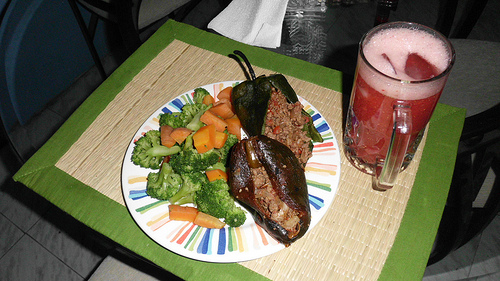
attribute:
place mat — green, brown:
[9, 15, 470, 279]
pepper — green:
[230, 48, 322, 165]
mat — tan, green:
[92, 43, 480, 280]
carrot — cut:
[173, 127, 187, 142]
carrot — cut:
[160, 125, 173, 142]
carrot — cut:
[193, 129, 213, 151]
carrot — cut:
[201, 113, 226, 131]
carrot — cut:
[205, 165, 225, 184]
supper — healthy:
[132, 70, 324, 233]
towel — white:
[206, 2, 291, 50]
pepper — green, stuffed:
[229, 69, 326, 164]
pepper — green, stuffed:
[225, 134, 312, 245]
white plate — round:
[136, 46, 359, 267]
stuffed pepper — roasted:
[226, 45, 329, 164]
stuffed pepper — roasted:
[223, 132, 313, 248]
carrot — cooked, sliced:
[167, 200, 224, 230]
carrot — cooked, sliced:
[201, 165, 228, 182]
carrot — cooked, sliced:
[158, 121, 188, 146]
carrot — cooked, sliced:
[193, 85, 244, 152]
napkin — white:
[206, 0, 288, 49]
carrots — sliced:
[196, 87, 253, 152]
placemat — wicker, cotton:
[4, 16, 464, 278]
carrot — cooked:
[190, 122, 215, 152]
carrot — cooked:
[167, 125, 192, 145]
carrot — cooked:
[191, 211, 225, 230]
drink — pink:
[350, 29, 448, 169]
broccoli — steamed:
[133, 85, 243, 223]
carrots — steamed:
[161, 85, 238, 226]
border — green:
[14, 19, 464, 278]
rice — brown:
[263, 80, 310, 163]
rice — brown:
[250, 168, 299, 235]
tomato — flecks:
[266, 89, 283, 135]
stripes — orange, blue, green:
[130, 83, 333, 256]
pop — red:
[353, 30, 446, 171]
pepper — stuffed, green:
[231, 51, 316, 171]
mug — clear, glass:
[344, 20, 454, 190]